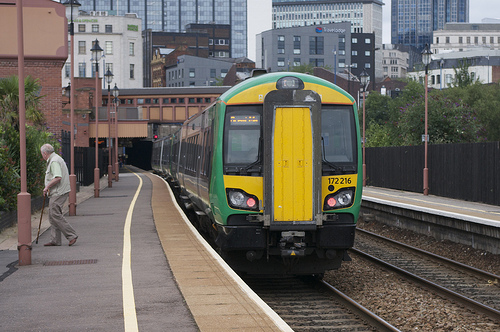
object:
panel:
[269, 105, 316, 225]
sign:
[274, 75, 304, 91]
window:
[321, 109, 353, 163]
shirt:
[44, 152, 72, 199]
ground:
[429, 195, 449, 209]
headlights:
[226, 190, 354, 211]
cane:
[35, 192, 47, 244]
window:
[128, 41, 134, 80]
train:
[151, 70, 363, 282]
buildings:
[142, 23, 236, 88]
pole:
[362, 87, 365, 187]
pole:
[422, 71, 429, 196]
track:
[242, 227, 500, 332]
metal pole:
[112, 103, 119, 182]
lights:
[230, 116, 259, 124]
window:
[226, 106, 259, 166]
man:
[39, 143, 79, 247]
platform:
[0, 164, 296, 332]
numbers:
[328, 177, 353, 185]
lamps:
[13, 0, 34, 265]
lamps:
[61, 0, 81, 216]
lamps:
[89, 37, 105, 197]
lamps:
[111, 83, 121, 182]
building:
[60, 0, 144, 89]